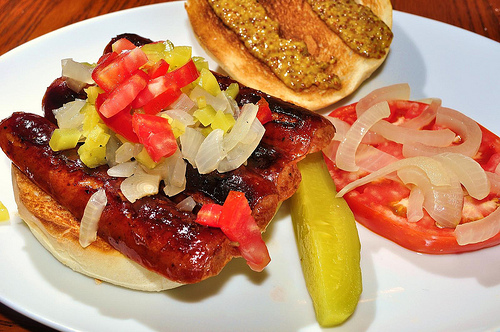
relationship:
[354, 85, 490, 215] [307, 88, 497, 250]
onions are on top of tomato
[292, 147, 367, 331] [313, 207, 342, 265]
pickle has seeds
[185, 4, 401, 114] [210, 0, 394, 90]
bread has sauce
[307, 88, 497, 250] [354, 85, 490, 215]
tomato has onions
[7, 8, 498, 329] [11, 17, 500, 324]
plate has food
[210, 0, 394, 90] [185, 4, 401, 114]
sauce of bread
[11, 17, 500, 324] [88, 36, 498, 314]
sadwich has toppigs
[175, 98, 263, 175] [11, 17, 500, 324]
onions of sadwich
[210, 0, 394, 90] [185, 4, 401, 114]
spread of top bu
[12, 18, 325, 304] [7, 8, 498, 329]
sadwich of plate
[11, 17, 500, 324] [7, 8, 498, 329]
food of plate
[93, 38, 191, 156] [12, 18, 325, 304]
tomato of sadwich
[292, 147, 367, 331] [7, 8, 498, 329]
pickle of plate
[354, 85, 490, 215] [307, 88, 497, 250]
onions are o tomato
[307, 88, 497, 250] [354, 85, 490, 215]
tomato under onions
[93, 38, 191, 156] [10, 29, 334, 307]
tomato of sausage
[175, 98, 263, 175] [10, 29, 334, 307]
onions are o sausage